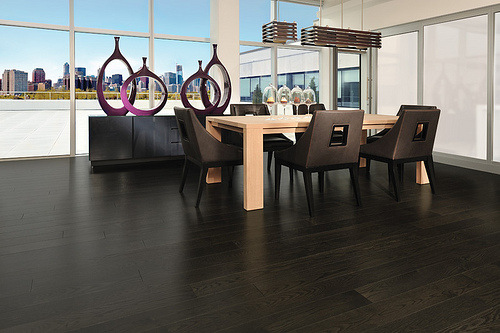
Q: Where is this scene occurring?
A: Dining room in high rise apartment.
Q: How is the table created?
A: Out of wood.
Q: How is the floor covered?
A: In dark wood laminate flooring.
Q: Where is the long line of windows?
A: Behind dining table and sculptures.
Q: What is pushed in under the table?
A: Chairs.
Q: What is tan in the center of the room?
A: The table.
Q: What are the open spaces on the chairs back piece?
A: Holes.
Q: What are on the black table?
A: Art pieces.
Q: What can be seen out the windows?
A: Buildings.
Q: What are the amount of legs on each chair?
A: 4.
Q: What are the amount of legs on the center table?
A: 4.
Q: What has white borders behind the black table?
A: Windows.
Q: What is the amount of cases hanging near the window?
A: 2.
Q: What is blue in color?
A: The sky.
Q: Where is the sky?
A: Outside the window.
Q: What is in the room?
A: Chairs and a table.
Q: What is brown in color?
A: The table.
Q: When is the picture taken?
A: Daytime.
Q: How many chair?
A: 6.